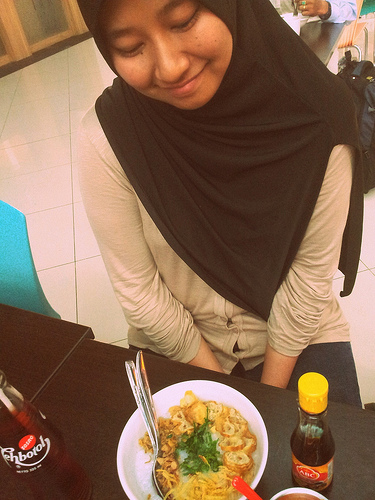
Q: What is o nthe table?
A: Soda.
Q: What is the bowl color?
A: White.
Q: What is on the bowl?
A: Spoons.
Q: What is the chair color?
A: Blue.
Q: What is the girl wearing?
A: A burka.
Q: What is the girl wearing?
A: A black cover.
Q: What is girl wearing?
A: A brown shirt.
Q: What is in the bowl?
A: Silver spoon.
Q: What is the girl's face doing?
A: Smiling.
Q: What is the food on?
A: A table.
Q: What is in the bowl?
A: Yellow food.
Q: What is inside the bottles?
A: Liquid.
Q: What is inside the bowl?
A: Food.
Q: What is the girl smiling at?
A: Her food.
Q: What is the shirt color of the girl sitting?
A: Brown.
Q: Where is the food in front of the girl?
A: On a white plate.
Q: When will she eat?
A: Shortly.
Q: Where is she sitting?
A: At the table.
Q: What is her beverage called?
A: Tehbotol.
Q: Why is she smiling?
A: Happiness.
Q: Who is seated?
A: A woman.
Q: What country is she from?
A: Middle east.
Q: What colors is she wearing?
A: Brown and tan.